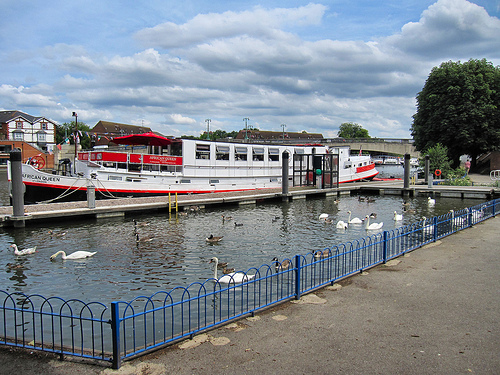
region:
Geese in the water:
[280, 212, 395, 243]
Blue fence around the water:
[148, 299, 213, 335]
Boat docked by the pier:
[10, 121, 402, 209]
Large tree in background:
[419, 37, 491, 138]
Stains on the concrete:
[235, 281, 360, 363]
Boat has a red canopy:
[85, 123, 177, 155]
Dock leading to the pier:
[355, 160, 495, 195]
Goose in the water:
[184, 225, 230, 247]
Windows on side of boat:
[161, 125, 338, 188]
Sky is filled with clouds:
[108, 24, 353, 139]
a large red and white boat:
[9, 120, 383, 198]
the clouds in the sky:
[13, 6, 467, 125]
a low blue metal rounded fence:
[2, 219, 428, 364]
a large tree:
[402, 57, 497, 171]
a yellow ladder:
[164, 191, 184, 218]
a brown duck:
[204, 232, 222, 244]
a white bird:
[205, 252, 250, 285]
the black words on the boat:
[21, 170, 64, 185]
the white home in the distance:
[3, 105, 60, 155]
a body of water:
[2, 193, 457, 315]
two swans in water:
[8, 240, 101, 271]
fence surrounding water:
[3, 267, 205, 362]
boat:
[12, 110, 378, 211]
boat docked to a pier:
[3, 124, 380, 216]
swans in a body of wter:
[0, 192, 380, 274]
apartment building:
[3, 96, 59, 142]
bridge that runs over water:
[340, 126, 425, 161]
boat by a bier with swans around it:
[7, 98, 492, 338]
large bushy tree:
[415, 68, 496, 173]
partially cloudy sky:
[106, 70, 341, 117]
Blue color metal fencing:
[105, 245, 360, 323]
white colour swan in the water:
[50, 247, 114, 267]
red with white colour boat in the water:
[0, 126, 403, 223]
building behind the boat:
[3, 108, 64, 145]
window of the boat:
[193, 136, 345, 163]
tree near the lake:
[403, 73, 493, 176]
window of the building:
[36, 129, 49, 141]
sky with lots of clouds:
[148, 45, 375, 109]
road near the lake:
[275, 310, 472, 347]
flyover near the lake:
[201, 128, 418, 154]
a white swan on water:
[9, 242, 39, 256]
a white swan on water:
[206, 255, 253, 284]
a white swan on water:
[335, 220, 348, 229]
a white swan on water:
[345, 210, 363, 225]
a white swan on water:
[361, 212, 384, 232]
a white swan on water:
[390, 208, 403, 222]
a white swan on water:
[419, 215, 434, 232]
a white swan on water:
[425, 193, 437, 205]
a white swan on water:
[446, 207, 464, 223]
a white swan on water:
[471, 202, 488, 218]